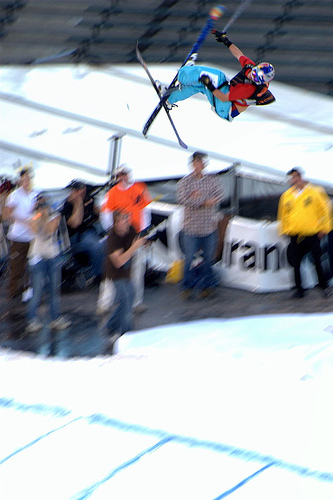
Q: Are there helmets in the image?
A: Yes, there is a helmet.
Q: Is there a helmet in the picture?
A: Yes, there is a helmet.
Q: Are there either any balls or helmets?
A: Yes, there is a helmet.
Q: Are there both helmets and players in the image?
A: No, there is a helmet but no players.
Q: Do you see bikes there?
A: No, there are no bikes.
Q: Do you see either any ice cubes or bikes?
A: No, there are no bikes or ice cubes.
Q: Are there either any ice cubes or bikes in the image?
A: No, there are no bikes or ice cubes.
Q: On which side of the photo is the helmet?
A: The helmet is on the right of the image.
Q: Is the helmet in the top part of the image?
A: Yes, the helmet is in the top of the image.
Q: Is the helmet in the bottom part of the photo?
A: No, the helmet is in the top of the image.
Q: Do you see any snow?
A: Yes, there is snow.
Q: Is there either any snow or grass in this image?
A: Yes, there is snow.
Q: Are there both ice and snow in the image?
A: No, there is snow but no ice.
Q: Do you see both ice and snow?
A: No, there is snow but no ice.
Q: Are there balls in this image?
A: No, there are no balls.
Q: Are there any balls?
A: No, there are no balls.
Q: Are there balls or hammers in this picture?
A: No, there are no balls or hammers.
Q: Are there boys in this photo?
A: No, there are no boys.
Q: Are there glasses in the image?
A: No, there are no glasses.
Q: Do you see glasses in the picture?
A: No, there are no glasses.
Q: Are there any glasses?
A: No, there are no glasses.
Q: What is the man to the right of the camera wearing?
A: The man is wearing a shirt.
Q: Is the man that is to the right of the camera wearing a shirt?
A: Yes, the man is wearing a shirt.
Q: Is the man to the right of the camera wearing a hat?
A: No, the man is wearing a shirt.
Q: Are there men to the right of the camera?
A: Yes, there is a man to the right of the camera.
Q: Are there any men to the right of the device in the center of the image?
A: Yes, there is a man to the right of the camera.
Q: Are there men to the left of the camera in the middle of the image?
A: No, the man is to the right of the camera.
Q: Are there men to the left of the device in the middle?
A: No, the man is to the right of the camera.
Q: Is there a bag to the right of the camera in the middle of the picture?
A: No, there is a man to the right of the camera.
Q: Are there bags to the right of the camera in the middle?
A: No, there is a man to the right of the camera.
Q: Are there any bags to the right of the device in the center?
A: No, there is a man to the right of the camera.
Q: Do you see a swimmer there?
A: No, there are no swimmers.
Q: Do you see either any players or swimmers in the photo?
A: No, there are no swimmers or players.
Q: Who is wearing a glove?
A: The man is wearing a glove.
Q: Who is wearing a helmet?
A: The man is wearing a helmet.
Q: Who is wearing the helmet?
A: The man is wearing a helmet.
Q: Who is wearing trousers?
A: The man is wearing trousers.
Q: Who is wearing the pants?
A: The man is wearing trousers.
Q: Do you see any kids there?
A: No, there are no kids.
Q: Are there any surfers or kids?
A: No, there are no kids or surfers.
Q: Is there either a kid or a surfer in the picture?
A: No, there are no children or surfers.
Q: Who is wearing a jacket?
A: The man is wearing a jacket.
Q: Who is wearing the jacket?
A: The man is wearing a jacket.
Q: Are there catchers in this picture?
A: No, there are no catchers.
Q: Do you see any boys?
A: No, there are no boys.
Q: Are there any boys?
A: No, there are no boys.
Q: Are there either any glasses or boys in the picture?
A: No, there are no boys or glasses.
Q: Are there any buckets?
A: No, there are no buckets.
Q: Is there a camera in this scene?
A: Yes, there is a camera.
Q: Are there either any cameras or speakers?
A: Yes, there is a camera.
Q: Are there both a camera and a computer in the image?
A: No, there is a camera but no computers.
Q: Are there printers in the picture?
A: No, there are no printers.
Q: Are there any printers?
A: No, there are no printers.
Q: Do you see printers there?
A: No, there are no printers.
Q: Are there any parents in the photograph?
A: No, there are no parents.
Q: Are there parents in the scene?
A: No, there are no parents.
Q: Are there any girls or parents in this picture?
A: No, there are no parents or girls.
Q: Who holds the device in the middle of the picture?
A: The man holds the camera.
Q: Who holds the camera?
A: The man holds the camera.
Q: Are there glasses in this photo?
A: No, there are no glasses.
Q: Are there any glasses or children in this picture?
A: No, there are no glasses or children.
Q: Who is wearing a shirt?
A: The man is wearing a shirt.